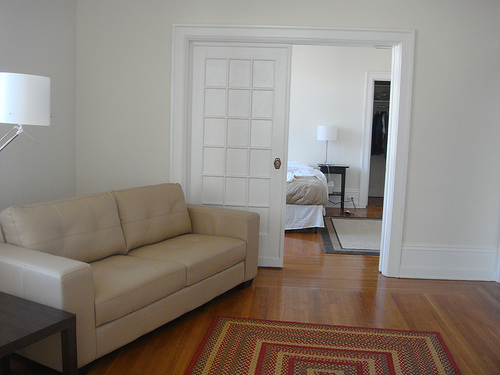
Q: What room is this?
A: It is a living room.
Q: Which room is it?
A: It is a living room.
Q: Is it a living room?
A: Yes, it is a living room.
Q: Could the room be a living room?
A: Yes, it is a living room.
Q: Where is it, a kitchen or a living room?
A: It is a living room.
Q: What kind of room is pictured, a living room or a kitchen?
A: It is a living room.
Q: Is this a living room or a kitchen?
A: It is a living room.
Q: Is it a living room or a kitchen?
A: It is a living room.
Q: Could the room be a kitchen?
A: No, it is a living room.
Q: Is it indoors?
A: Yes, it is indoors.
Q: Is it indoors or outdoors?
A: It is indoors.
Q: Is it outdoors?
A: No, it is indoors.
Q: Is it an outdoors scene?
A: No, it is indoors.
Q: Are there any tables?
A: Yes, there is a table.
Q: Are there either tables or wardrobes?
A: Yes, there is a table.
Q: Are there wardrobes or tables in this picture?
A: Yes, there is a table.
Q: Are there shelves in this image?
A: No, there are no shelves.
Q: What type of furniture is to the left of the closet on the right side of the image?
A: The piece of furniture is a table.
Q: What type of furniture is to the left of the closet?
A: The piece of furniture is a table.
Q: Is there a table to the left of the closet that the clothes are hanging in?
A: Yes, there is a table to the left of the closet.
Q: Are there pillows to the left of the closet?
A: No, there is a table to the left of the closet.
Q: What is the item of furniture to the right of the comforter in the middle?
A: The piece of furniture is a table.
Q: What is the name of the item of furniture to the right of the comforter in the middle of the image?
A: The piece of furniture is a table.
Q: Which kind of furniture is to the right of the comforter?
A: The piece of furniture is a table.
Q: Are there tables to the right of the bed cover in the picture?
A: Yes, there is a table to the right of the bed cover.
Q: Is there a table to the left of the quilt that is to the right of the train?
A: No, the table is to the right of the comforter.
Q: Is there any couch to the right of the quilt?
A: No, there is a table to the right of the quilt.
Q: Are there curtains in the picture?
A: No, there are no curtains.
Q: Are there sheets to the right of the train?
A: Yes, there are sheets to the right of the train.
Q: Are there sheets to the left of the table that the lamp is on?
A: Yes, there are sheets to the left of the table.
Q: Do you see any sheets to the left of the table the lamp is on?
A: Yes, there are sheets to the left of the table.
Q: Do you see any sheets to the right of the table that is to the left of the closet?
A: No, the sheets are to the left of the table.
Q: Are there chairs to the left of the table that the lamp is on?
A: No, there are sheets to the left of the table.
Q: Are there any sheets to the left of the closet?
A: Yes, there are sheets to the left of the closet.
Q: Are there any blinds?
A: No, there are no blinds.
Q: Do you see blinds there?
A: No, there are no blinds.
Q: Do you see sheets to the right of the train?
A: Yes, there are sheets to the right of the train.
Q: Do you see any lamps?
A: Yes, there is a lamp.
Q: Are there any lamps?
A: Yes, there is a lamp.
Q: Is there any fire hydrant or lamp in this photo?
A: Yes, there is a lamp.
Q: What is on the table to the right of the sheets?
A: The lamp is on the table.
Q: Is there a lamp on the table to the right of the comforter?
A: Yes, there is a lamp on the table.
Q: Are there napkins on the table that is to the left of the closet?
A: No, there is a lamp on the table.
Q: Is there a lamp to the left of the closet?
A: Yes, there is a lamp to the left of the closet.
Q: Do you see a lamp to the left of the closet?
A: Yes, there is a lamp to the left of the closet.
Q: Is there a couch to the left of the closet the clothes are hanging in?
A: No, there is a lamp to the left of the closet.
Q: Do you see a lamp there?
A: Yes, there is a lamp.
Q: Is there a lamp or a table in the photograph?
A: Yes, there is a lamp.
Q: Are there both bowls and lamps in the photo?
A: No, there is a lamp but no bowls.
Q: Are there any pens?
A: No, there are no pens.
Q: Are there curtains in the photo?
A: No, there are no curtains.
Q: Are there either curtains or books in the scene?
A: No, there are no curtains or books.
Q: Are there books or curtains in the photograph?
A: No, there are no curtains or books.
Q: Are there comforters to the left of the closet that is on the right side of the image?
A: Yes, there is a comforter to the left of the closet.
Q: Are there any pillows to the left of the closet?
A: No, there is a comforter to the left of the closet.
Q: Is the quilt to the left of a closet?
A: Yes, the quilt is to the left of a closet.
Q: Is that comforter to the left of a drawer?
A: No, the comforter is to the left of a closet.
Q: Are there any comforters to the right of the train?
A: Yes, there is a comforter to the right of the train.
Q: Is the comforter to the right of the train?
A: Yes, the comforter is to the right of the train.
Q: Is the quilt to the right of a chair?
A: No, the quilt is to the right of the train.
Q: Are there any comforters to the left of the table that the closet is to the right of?
A: Yes, there is a comforter to the left of the table.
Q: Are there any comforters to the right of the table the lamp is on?
A: No, the comforter is to the left of the table.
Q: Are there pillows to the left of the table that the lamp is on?
A: No, there is a comforter to the left of the table.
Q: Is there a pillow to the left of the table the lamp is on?
A: No, there is a comforter to the left of the table.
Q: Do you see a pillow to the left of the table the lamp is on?
A: No, there is a comforter to the left of the table.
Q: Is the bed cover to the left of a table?
A: Yes, the bed cover is to the left of a table.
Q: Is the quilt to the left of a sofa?
A: No, the quilt is to the left of a table.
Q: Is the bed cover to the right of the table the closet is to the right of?
A: No, the bed cover is to the left of the table.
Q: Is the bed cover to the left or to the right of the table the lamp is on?
A: The bed cover is to the left of the table.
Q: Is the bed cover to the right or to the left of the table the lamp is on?
A: The bed cover is to the left of the table.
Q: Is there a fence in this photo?
A: No, there are no fences.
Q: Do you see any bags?
A: No, there are no bags.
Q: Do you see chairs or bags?
A: No, there are no bags or chairs.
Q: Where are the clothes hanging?
A: The clothes are hanging in the closet.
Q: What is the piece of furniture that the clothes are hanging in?
A: The piece of furniture is a closet.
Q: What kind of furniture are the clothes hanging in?
A: The clothes are hanging in the closet.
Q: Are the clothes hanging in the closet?
A: Yes, the clothes are hanging in the closet.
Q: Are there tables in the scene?
A: Yes, there is a table.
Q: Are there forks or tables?
A: Yes, there is a table.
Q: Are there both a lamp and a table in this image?
A: Yes, there are both a table and a lamp.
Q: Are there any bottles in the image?
A: No, there are no bottles.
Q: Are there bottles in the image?
A: No, there are no bottles.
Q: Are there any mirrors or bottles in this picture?
A: No, there are no bottles or mirrors.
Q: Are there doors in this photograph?
A: Yes, there is a door.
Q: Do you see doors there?
A: Yes, there is a door.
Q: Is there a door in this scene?
A: Yes, there is a door.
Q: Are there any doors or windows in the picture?
A: Yes, there is a door.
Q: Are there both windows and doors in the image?
A: Yes, there are both a door and a window.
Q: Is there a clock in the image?
A: No, there are no clocks.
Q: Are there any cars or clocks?
A: No, there are no clocks or cars.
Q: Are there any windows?
A: Yes, there is a window.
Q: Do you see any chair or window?
A: Yes, there is a window.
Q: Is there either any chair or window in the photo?
A: Yes, there is a window.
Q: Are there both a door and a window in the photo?
A: Yes, there are both a window and a door.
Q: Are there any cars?
A: No, there are no cars.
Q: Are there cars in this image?
A: No, there are no cars.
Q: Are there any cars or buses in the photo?
A: No, there are no cars or buses.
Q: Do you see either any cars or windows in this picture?
A: Yes, there is a window.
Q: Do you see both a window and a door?
A: Yes, there are both a window and a door.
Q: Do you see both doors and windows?
A: Yes, there are both a window and a door.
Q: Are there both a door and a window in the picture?
A: Yes, there are both a window and a door.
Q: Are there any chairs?
A: No, there are no chairs.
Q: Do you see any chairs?
A: No, there are no chairs.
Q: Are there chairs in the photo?
A: No, there are no chairs.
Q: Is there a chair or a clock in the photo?
A: No, there are no chairs or clocks.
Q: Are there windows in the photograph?
A: Yes, there is a window.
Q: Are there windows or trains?
A: Yes, there is a window.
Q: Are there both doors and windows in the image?
A: Yes, there are both a window and a door.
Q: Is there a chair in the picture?
A: No, there are no chairs.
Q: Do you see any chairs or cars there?
A: No, there are no chairs or cars.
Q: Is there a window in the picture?
A: Yes, there is a window.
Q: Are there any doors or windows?
A: Yes, there is a window.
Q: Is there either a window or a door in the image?
A: Yes, there is a window.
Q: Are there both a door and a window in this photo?
A: Yes, there are both a window and a door.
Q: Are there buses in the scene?
A: No, there are no buses.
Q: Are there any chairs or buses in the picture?
A: No, there are no buses or chairs.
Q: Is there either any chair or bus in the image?
A: No, there are no buses or chairs.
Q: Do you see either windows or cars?
A: Yes, there is a window.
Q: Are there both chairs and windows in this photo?
A: No, there is a window but no chairs.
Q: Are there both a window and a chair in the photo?
A: No, there is a window but no chairs.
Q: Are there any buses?
A: No, there are no buses.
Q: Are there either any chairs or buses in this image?
A: No, there are no buses or chairs.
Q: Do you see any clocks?
A: No, there are no clocks.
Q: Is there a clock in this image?
A: No, there are no clocks.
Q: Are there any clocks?
A: No, there are no clocks.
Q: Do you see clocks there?
A: No, there are no clocks.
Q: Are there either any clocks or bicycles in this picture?
A: No, there are no clocks or bicycles.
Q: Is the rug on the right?
A: Yes, the rug is on the right of the image.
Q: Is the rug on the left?
A: No, the rug is on the right of the image.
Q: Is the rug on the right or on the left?
A: The rug is on the right of the image.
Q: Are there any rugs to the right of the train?
A: Yes, there is a rug to the right of the train.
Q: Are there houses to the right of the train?
A: No, there is a rug to the right of the train.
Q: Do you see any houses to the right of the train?
A: No, there is a rug to the right of the train.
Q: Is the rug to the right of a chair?
A: No, the rug is to the right of a train.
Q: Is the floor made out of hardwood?
A: Yes, the floor is made of hardwood.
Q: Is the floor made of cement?
A: No, the floor is made of hardwood.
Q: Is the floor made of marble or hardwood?
A: The floor is made of hardwood.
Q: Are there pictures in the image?
A: No, there are no pictures.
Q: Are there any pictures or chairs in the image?
A: No, there are no pictures or chairs.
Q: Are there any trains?
A: Yes, there is a train.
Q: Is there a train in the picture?
A: Yes, there is a train.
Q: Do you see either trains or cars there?
A: Yes, there is a train.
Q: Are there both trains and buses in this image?
A: No, there is a train but no buses.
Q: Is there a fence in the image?
A: No, there are no fences.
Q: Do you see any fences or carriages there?
A: No, there are no fences or carriages.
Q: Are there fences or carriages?
A: No, there are no fences or carriages.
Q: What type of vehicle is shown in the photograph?
A: The vehicle is a train.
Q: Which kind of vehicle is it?
A: The vehicle is a train.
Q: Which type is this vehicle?
A: This is a train.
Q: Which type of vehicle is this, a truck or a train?
A: This is a train.